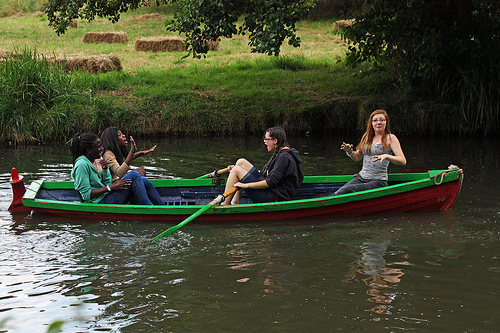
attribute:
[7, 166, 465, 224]
row boat — canoe, red, green, green on top, red underneath, raft, trimmed green, blue inside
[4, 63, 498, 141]
shore — over grown, grassy, green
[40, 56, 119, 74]
haystack — brown, pile of hay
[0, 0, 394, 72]
field — grassy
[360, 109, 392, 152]
hair — red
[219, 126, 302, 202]
woman — young, rowing boat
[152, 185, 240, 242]
oar — green colored, green, painted green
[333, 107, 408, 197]
woman — red headed, facing camera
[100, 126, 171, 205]
woman — talking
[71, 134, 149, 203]
woman — laughing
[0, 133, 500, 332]
water — reflecting, calm, reflective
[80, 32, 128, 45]
haystack — here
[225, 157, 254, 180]
knees — bent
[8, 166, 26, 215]
rutter — red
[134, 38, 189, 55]
bale of hay — pile of hay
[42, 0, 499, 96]
tree — green